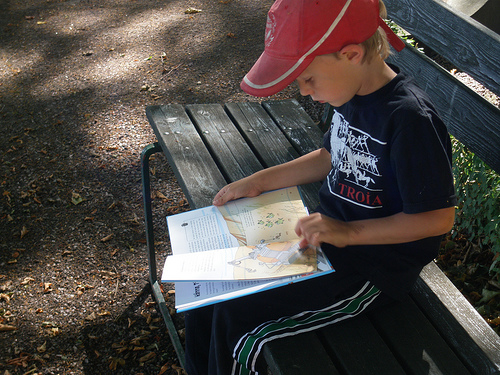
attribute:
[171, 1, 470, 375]
boy — young, small, holding, reading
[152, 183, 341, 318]
book — designed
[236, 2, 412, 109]
hat — striped, red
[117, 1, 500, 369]
bench — supported, wooden, iron, brown, old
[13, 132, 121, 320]
leaves — falling, brown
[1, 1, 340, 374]
ground — sandy, rocky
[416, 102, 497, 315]
bush — small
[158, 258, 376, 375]
pants — black